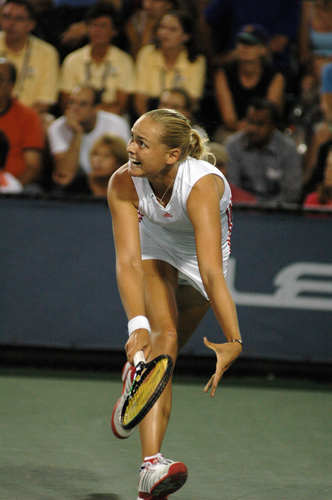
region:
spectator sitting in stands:
[67, 135, 120, 195]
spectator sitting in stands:
[202, 141, 254, 203]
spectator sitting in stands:
[216, 100, 304, 204]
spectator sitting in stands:
[210, 25, 285, 139]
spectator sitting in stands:
[136, 7, 201, 101]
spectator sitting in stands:
[59, 15, 132, 110]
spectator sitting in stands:
[0, 0, 58, 122]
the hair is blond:
[142, 107, 215, 165]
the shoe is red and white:
[137, 452, 187, 498]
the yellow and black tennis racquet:
[118, 349, 173, 430]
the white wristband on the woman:
[127, 315, 151, 334]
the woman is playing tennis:
[106, 108, 242, 498]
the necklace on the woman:
[152, 176, 175, 206]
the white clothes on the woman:
[130, 155, 231, 302]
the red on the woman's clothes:
[136, 196, 232, 265]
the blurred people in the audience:
[0, 1, 331, 208]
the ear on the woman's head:
[166, 148, 180, 164]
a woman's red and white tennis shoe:
[133, 454, 188, 499]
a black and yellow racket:
[120, 336, 170, 428]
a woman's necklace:
[148, 173, 176, 207]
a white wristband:
[124, 313, 151, 334]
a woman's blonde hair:
[141, 107, 215, 167]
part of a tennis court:
[176, 390, 331, 499]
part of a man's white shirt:
[49, 108, 129, 170]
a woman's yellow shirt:
[139, 47, 205, 100]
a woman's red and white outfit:
[106, 156, 233, 297]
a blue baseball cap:
[234, 20, 270, 46]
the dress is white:
[122, 170, 236, 302]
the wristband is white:
[122, 308, 158, 341]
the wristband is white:
[125, 313, 153, 333]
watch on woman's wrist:
[230, 333, 245, 347]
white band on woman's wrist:
[125, 316, 149, 330]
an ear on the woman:
[165, 149, 179, 163]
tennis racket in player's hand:
[121, 350, 169, 427]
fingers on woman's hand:
[201, 333, 238, 397]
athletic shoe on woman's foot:
[137, 455, 186, 498]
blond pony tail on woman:
[191, 127, 212, 161]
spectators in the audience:
[226, 1, 330, 205]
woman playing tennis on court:
[84, 107, 245, 497]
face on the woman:
[126, 121, 162, 176]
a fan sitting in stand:
[55, 83, 121, 177]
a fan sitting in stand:
[86, 132, 137, 189]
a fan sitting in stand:
[227, 99, 296, 187]